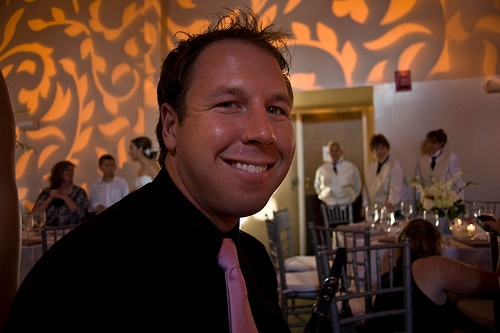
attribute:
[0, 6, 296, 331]
man — smiling 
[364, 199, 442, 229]
goblets — full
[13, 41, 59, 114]
design — orange 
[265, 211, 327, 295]
chairs — empty 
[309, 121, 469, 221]
waiters — standing